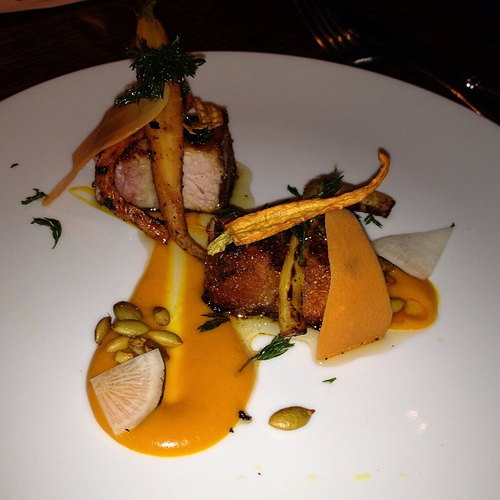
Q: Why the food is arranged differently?
A: To make it presentable.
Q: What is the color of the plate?
A: White.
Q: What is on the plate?
A: Food.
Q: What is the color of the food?
A: Yellow, brown and white.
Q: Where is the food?
A: On the plate.